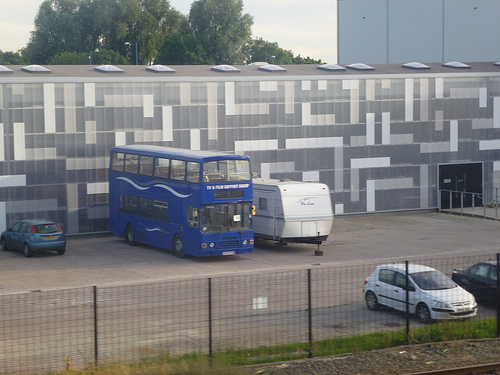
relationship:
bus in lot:
[128, 112, 254, 262] [75, 216, 373, 321]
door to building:
[416, 153, 469, 204] [299, 38, 489, 185]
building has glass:
[299, 38, 489, 185] [263, 99, 292, 140]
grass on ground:
[283, 334, 317, 360] [261, 306, 382, 366]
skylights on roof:
[123, 49, 271, 83] [169, 68, 328, 97]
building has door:
[299, 38, 489, 185] [433, 161, 489, 211]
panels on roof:
[29, 57, 124, 92] [169, 68, 328, 97]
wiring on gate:
[124, 284, 221, 351] [104, 307, 271, 374]